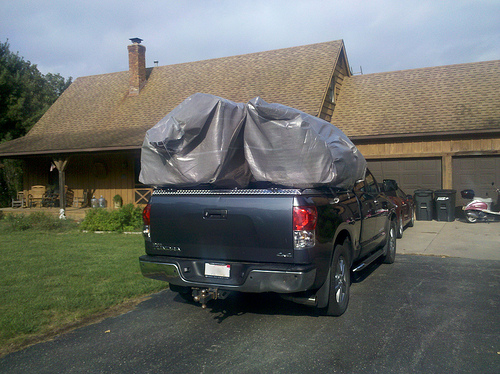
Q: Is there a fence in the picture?
A: No, there are no fences.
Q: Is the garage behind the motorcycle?
A: Yes, the garage is behind the motorcycle.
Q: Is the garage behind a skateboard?
A: No, the garage is behind the motorcycle.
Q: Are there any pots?
A: No, there are no pots.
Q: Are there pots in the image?
A: No, there are no pots.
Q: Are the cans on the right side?
A: Yes, the cans are on the right of the image.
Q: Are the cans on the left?
A: No, the cans are on the right of the image.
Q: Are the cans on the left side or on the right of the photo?
A: The cans are on the right of the image.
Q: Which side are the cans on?
A: The cans are on the right of the image.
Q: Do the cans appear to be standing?
A: Yes, the cans are standing.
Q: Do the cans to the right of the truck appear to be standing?
A: Yes, the cans are standing.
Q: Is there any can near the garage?
A: Yes, there are cans near the garage.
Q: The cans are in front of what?
A: The cans are in front of the garage.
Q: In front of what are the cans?
A: The cans are in front of the garage.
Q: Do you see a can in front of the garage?
A: Yes, there are cans in front of the garage.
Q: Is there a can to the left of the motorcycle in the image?
A: Yes, there are cans to the left of the motorcycle.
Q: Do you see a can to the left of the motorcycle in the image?
A: Yes, there are cans to the left of the motorcycle.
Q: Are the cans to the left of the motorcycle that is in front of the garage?
A: Yes, the cans are to the left of the motorcycle.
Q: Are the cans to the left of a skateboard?
A: No, the cans are to the left of the motorcycle.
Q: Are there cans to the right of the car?
A: Yes, there are cans to the right of the car.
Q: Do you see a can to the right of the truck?
A: Yes, there are cans to the right of the truck.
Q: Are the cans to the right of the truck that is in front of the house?
A: Yes, the cans are to the right of the truck.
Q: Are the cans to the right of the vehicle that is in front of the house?
A: Yes, the cans are to the right of the truck.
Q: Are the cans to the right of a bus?
A: No, the cans are to the right of the truck.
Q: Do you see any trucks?
A: Yes, there is a truck.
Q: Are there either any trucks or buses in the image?
A: Yes, there is a truck.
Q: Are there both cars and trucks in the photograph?
A: Yes, there are both a truck and cars.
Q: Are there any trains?
A: No, there are no trains.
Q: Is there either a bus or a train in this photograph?
A: No, there are no trains or buses.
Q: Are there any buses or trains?
A: No, there are no trains or buses.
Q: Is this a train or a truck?
A: This is a truck.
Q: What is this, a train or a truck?
A: This is a truck.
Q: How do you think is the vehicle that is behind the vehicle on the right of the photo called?
A: The vehicle is a truck.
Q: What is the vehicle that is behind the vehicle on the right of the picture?
A: The vehicle is a truck.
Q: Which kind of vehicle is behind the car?
A: The vehicle is a truck.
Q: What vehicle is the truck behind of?
A: The truck is behind the car.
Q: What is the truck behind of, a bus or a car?
A: The truck is behind a car.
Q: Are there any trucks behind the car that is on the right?
A: Yes, there is a truck behind the car.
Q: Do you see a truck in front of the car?
A: No, the truck is behind the car.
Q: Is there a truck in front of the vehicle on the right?
A: No, the truck is behind the car.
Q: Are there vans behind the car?
A: No, there is a truck behind the car.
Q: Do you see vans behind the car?
A: No, there is a truck behind the car.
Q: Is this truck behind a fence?
A: No, the truck is behind a car.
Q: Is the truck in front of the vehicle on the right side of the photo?
A: No, the truck is behind the car.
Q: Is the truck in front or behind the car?
A: The truck is behind the car.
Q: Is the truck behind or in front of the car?
A: The truck is behind the car.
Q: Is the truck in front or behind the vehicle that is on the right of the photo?
A: The truck is behind the car.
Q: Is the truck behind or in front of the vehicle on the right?
A: The truck is behind the car.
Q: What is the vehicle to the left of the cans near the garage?
A: The vehicle is a truck.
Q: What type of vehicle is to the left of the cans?
A: The vehicle is a truck.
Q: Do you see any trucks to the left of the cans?
A: Yes, there is a truck to the left of the cans.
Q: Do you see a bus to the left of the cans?
A: No, there is a truck to the left of the cans.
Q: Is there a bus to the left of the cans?
A: No, there is a truck to the left of the cans.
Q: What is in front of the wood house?
A: The truck is in front of the house.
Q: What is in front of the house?
A: The truck is in front of the house.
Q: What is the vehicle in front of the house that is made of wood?
A: The vehicle is a truck.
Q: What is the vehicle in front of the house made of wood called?
A: The vehicle is a truck.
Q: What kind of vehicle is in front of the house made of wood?
A: The vehicle is a truck.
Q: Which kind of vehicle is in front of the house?
A: The vehicle is a truck.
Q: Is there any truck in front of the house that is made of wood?
A: Yes, there is a truck in front of the house.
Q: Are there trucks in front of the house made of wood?
A: Yes, there is a truck in front of the house.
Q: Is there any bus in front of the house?
A: No, there is a truck in front of the house.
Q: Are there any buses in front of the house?
A: No, there is a truck in front of the house.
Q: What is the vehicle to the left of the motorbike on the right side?
A: The vehicle is a truck.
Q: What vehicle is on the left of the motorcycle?
A: The vehicle is a truck.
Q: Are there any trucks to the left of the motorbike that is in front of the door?
A: Yes, there is a truck to the left of the motorbike.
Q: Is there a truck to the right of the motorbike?
A: No, the truck is to the left of the motorbike.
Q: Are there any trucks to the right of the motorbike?
A: No, the truck is to the left of the motorbike.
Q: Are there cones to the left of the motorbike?
A: No, there is a truck to the left of the motorbike.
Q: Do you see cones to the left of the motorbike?
A: No, there is a truck to the left of the motorbike.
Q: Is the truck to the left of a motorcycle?
A: Yes, the truck is to the left of a motorcycle.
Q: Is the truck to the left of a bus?
A: No, the truck is to the left of a motorcycle.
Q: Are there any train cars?
A: No, there are no train cars.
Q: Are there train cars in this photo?
A: No, there are no train cars.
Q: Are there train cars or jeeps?
A: No, there are no train cars or jeeps.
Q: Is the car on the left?
A: No, the car is on the right of the image.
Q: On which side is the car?
A: The car is on the right of the image.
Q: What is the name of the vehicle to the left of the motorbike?
A: The vehicle is a car.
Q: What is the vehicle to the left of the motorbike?
A: The vehicle is a car.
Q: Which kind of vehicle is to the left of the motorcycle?
A: The vehicle is a car.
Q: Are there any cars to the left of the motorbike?
A: Yes, there is a car to the left of the motorbike.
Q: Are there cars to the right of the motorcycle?
A: No, the car is to the left of the motorcycle.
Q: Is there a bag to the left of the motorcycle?
A: No, there is a car to the left of the motorcycle.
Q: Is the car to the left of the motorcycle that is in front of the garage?
A: Yes, the car is to the left of the motorcycle.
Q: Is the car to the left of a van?
A: No, the car is to the left of the motorcycle.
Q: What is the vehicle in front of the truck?
A: The vehicle is a car.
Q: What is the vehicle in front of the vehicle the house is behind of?
A: The vehicle is a car.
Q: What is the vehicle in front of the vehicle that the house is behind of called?
A: The vehicle is a car.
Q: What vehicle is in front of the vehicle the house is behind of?
A: The vehicle is a car.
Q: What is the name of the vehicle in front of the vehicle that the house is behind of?
A: The vehicle is a car.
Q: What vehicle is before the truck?
A: The vehicle is a car.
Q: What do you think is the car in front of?
A: The car is in front of the truck.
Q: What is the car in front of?
A: The car is in front of the truck.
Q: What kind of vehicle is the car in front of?
A: The car is in front of the truck.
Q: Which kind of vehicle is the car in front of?
A: The car is in front of the truck.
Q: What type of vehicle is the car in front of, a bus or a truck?
A: The car is in front of a truck.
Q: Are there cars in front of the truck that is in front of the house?
A: Yes, there is a car in front of the truck.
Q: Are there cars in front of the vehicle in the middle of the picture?
A: Yes, there is a car in front of the truck.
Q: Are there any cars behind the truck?
A: No, the car is in front of the truck.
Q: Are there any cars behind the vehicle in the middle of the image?
A: No, the car is in front of the truck.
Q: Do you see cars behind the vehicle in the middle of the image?
A: No, the car is in front of the truck.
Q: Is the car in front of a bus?
A: No, the car is in front of the truck.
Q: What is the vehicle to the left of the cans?
A: The vehicle is a car.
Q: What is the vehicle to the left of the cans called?
A: The vehicle is a car.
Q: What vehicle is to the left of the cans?
A: The vehicle is a car.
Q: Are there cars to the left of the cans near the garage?
A: Yes, there is a car to the left of the cans.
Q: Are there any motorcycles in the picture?
A: Yes, there is a motorcycle.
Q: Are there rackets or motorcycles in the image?
A: Yes, there is a motorcycle.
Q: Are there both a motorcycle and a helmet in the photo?
A: No, there is a motorcycle but no helmets.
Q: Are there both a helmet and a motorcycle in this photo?
A: No, there is a motorcycle but no helmets.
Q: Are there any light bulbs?
A: No, there are no light bulbs.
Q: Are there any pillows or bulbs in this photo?
A: No, there are no bulbs or pillows.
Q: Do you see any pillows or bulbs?
A: No, there are no bulbs or pillows.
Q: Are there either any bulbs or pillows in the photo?
A: No, there are no bulbs or pillows.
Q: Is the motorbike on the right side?
A: Yes, the motorbike is on the right of the image.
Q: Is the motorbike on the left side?
A: No, the motorbike is on the right of the image.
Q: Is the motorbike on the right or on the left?
A: The motorbike is on the right of the image.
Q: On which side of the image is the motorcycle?
A: The motorcycle is on the right of the image.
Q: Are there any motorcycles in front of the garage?
A: Yes, there is a motorcycle in front of the garage.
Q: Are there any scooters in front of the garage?
A: No, there is a motorcycle in front of the garage.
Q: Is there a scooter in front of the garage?
A: No, there is a motorcycle in front of the garage.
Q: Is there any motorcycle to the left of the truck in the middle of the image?
A: No, the motorcycle is to the right of the truck.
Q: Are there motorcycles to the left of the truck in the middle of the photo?
A: No, the motorcycle is to the right of the truck.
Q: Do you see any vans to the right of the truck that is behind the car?
A: No, there is a motorcycle to the right of the truck.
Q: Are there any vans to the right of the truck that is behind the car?
A: No, there is a motorcycle to the right of the truck.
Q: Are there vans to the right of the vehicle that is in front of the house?
A: No, there is a motorcycle to the right of the truck.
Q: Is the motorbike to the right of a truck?
A: Yes, the motorbike is to the right of a truck.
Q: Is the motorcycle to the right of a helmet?
A: No, the motorcycle is to the right of a truck.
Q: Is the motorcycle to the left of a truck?
A: No, the motorcycle is to the right of a truck.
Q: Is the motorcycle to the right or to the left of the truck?
A: The motorcycle is to the right of the truck.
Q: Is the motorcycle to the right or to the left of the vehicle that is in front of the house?
A: The motorcycle is to the right of the truck.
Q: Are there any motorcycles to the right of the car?
A: Yes, there is a motorcycle to the right of the car.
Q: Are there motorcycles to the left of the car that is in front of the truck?
A: No, the motorcycle is to the right of the car.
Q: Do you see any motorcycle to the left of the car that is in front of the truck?
A: No, the motorcycle is to the right of the car.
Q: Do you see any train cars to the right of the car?
A: No, there is a motorcycle to the right of the car.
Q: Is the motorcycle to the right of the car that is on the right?
A: Yes, the motorcycle is to the right of the car.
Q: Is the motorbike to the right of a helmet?
A: No, the motorbike is to the right of the car.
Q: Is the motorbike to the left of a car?
A: No, the motorbike is to the right of a car.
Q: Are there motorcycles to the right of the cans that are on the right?
A: Yes, there is a motorcycle to the right of the cans.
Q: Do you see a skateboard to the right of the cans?
A: No, there is a motorcycle to the right of the cans.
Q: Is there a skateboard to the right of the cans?
A: No, there is a motorcycle to the right of the cans.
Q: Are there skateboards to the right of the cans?
A: No, there is a motorcycle to the right of the cans.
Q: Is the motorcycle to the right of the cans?
A: Yes, the motorcycle is to the right of the cans.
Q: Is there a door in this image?
A: Yes, there is a door.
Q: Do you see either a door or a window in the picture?
A: Yes, there is a door.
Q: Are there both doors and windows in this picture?
A: No, there is a door but no windows.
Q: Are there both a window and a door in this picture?
A: No, there is a door but no windows.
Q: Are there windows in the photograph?
A: No, there are no windows.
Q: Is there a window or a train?
A: No, there are no windows or trains.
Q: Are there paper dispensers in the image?
A: No, there are no paper dispensers.